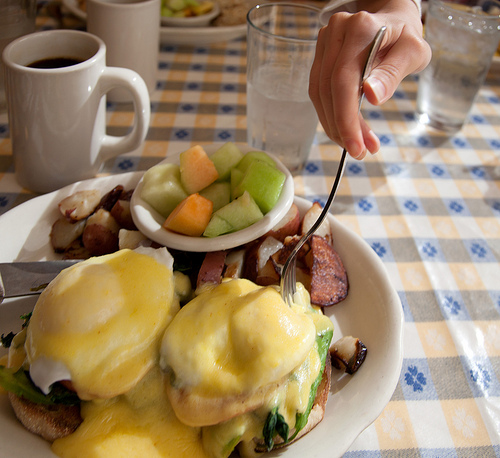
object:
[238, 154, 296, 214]
honeydew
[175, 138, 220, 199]
cantaloupe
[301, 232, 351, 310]
food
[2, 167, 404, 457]
plate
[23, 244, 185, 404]
eggs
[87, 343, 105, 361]
sauce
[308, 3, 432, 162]
hand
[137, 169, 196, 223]
fruit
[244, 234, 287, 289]
potatoes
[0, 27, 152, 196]
cup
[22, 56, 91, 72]
coffee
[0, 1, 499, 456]
tablecloth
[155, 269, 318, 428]
eggs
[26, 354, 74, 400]
bun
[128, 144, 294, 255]
bowl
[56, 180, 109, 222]
potatoes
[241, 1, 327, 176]
glass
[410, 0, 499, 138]
glass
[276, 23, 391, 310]
fork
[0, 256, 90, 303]
knife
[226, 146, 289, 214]
melon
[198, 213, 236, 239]
melon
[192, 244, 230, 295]
potatoes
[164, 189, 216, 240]
fruit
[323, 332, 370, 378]
food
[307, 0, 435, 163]
person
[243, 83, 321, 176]
water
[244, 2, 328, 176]
cup